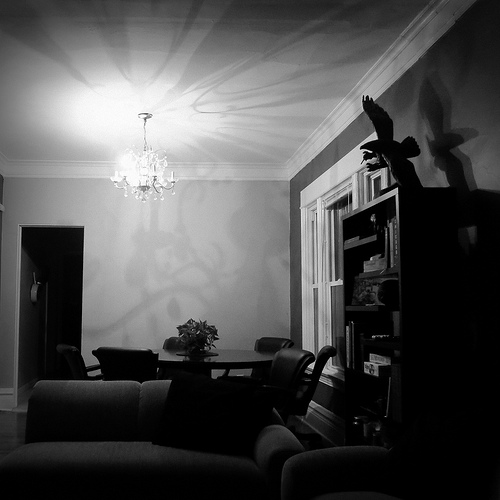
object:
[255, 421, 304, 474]
arm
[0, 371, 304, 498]
couch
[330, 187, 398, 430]
book shelf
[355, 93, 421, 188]
statue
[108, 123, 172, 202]
light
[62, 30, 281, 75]
ceiling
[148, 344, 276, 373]
table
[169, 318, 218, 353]
flowers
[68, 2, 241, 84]
reflection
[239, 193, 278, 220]
wall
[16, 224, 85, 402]
entryway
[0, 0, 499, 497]
room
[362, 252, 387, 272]
items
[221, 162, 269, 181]
molding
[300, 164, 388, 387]
window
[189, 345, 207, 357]
pot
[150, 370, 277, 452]
pillow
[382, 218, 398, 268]
books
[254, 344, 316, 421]
chairs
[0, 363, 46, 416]
doorway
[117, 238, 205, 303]
shadow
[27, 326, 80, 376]
kitchen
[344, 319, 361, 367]
box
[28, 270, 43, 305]
pan